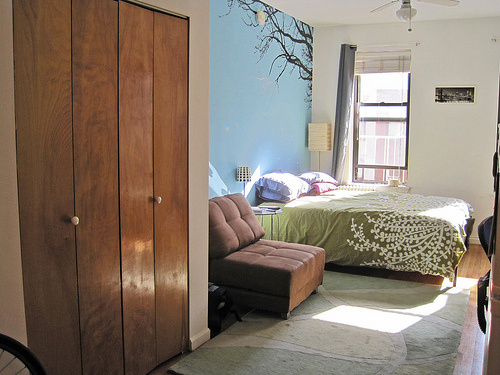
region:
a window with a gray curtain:
[330, 37, 422, 194]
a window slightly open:
[328, 40, 418, 184]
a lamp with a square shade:
[299, 115, 339, 177]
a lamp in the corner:
[291, 108, 338, 176]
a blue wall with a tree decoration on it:
[209, 5, 327, 180]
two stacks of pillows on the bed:
[255, 163, 347, 203]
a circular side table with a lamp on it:
[222, 160, 284, 244]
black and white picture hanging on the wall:
[422, 78, 485, 114]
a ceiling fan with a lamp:
[358, 0, 473, 34]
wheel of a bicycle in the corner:
[0, 325, 46, 373]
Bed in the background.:
[248, 160, 468, 285]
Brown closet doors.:
[15, 0, 196, 374]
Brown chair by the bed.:
[208, 185, 328, 317]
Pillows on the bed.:
[255, 165, 310, 205]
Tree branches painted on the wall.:
[218, 0, 313, 116]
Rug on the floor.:
[165, 262, 490, 372]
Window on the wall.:
[343, 40, 405, 186]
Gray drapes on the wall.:
[326, 37, 361, 182]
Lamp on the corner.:
[303, 116, 329, 172]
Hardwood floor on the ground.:
[454, 215, 486, 291]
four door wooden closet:
[13, 12, 212, 370]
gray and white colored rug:
[326, 277, 387, 372]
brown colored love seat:
[200, 200, 314, 324]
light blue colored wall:
[244, 45, 314, 175]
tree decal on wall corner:
[257, 29, 313, 106]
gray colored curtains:
[330, 49, 358, 186]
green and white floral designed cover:
[293, 185, 475, 276]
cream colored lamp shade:
[280, 108, 335, 162]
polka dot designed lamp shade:
[234, 158, 257, 189]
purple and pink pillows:
[279, 147, 334, 211]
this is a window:
[349, 79, 404, 135]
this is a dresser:
[95, 107, 162, 293]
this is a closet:
[71, 162, 191, 366]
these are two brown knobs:
[44, 184, 209, 219]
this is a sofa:
[243, 212, 280, 323]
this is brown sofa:
[246, 231, 315, 301]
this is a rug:
[301, 354, 314, 361]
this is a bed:
[270, 158, 472, 293]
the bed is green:
[341, 240, 371, 257]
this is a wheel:
[3, 227, 115, 372]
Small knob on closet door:
[152, 193, 162, 204]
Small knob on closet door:
[70, 215, 78, 225]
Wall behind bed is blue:
[212, 0, 314, 207]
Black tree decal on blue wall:
[215, 0, 313, 117]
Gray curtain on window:
[329, 39, 358, 179]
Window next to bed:
[351, 46, 411, 184]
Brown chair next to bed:
[210, 191, 327, 320]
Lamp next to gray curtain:
[306, 120, 332, 174]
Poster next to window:
[434, 85, 474, 102]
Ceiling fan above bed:
[367, 0, 459, 35]